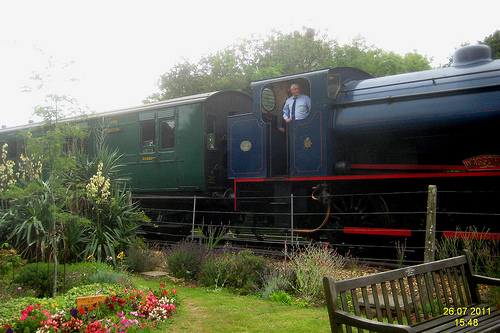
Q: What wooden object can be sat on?
A: The bench.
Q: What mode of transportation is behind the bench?
A: A train.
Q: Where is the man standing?
A: On the train.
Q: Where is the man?
A: On the train.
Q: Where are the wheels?
A: On the train.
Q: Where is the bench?
A: Beside the train.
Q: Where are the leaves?
A: On the tree.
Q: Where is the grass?
A: On the ground.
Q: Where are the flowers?
A: On the ground.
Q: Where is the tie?
A: On the man.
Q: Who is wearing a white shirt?
A: The man.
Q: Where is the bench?
A: On right.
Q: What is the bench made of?
A: Wood.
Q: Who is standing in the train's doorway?
A: Man.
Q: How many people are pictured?
A: 1.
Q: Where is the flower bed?
A: On left.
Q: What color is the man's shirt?
A: Light blue.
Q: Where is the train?
A: On track.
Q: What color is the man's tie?
A: Black.